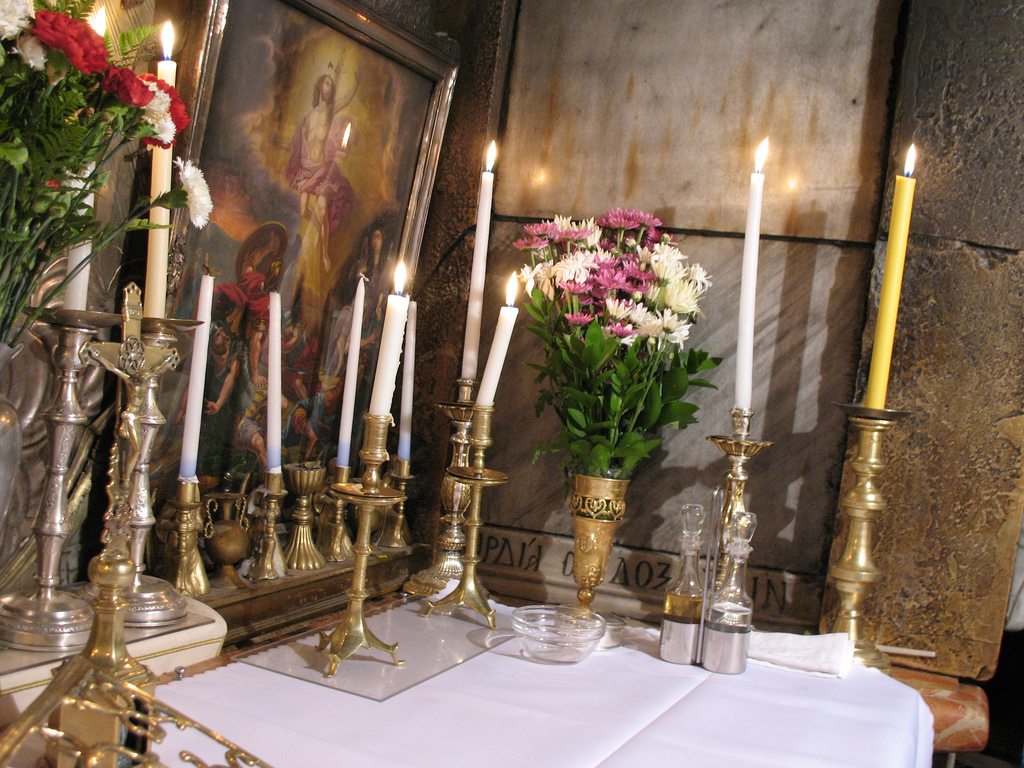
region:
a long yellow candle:
[829, 168, 932, 409]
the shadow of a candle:
[781, 217, 838, 434]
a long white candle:
[707, 180, 793, 414]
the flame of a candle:
[745, 124, 781, 182]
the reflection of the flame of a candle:
[774, 162, 820, 202]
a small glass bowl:
[505, 563, 605, 677]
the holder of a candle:
[326, 416, 418, 667]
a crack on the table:
[582, 660, 712, 760]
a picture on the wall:
[180, 10, 436, 467]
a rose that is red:
[31, 16, 112, 87]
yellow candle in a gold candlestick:
[817, 130, 926, 655]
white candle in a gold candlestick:
[706, 127, 777, 633]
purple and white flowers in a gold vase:
[501, 203, 716, 621]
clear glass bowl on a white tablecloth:
[507, 594, 607, 670]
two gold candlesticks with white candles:
[313, 253, 528, 666]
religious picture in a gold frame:
[150, 3, 461, 506]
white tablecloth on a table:
[140, 590, 960, 767]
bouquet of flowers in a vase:
[513, 198, 717, 606]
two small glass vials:
[652, 499, 760, 680]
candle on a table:
[857, 112, 962, 382]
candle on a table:
[706, 114, 812, 389]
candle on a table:
[487, 264, 549, 429]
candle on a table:
[375, 251, 420, 413]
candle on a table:
[242, 269, 320, 486]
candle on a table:
[182, 258, 227, 443]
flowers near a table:
[7, 35, 125, 169]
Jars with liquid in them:
[657, 499, 759, 674]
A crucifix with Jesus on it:
[80, 283, 178, 660]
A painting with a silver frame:
[159, 2, 457, 533]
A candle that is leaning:
[469, 279, 517, 407]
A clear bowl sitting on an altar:
[516, 606, 608, 661]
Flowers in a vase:
[516, 205, 726, 475]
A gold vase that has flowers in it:
[557, 466, 633, 645]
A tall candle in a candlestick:
[829, 142, 921, 658]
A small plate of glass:
[241, 574, 536, 698]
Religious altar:
[0, 0, 943, 766]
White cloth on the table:
[131, 583, 938, 765]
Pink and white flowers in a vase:
[511, 197, 711, 644]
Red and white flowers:
[2, 26, 209, 384]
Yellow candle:
[825, 122, 921, 673]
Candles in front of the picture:
[129, 15, 529, 706]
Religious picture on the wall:
[151, 0, 464, 564]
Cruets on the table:
[655, 485, 754, 688]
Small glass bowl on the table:
[509, 598, 605, 665]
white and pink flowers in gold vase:
[517, 186, 698, 481]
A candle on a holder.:
[464, 169, 506, 378]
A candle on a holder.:
[480, 292, 519, 406]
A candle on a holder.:
[740, 171, 756, 410]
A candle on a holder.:
[865, 163, 919, 410]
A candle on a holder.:
[258, 294, 287, 476]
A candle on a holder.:
[180, 258, 207, 477]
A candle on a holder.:
[152, 68, 163, 303]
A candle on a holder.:
[63, 57, 117, 307]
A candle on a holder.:
[265, 283, 288, 465]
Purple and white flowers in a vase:
[503, 212, 722, 627]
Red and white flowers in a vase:
[2, 3, 205, 551]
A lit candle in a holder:
[811, 148, 929, 664]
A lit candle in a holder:
[699, 135, 792, 641]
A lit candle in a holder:
[432, 275, 530, 614]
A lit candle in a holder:
[401, 132, 507, 589]